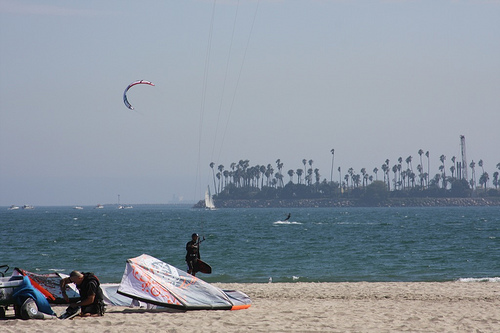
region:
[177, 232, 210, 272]
person wearing a black wet suit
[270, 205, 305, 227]
person water sailing in the water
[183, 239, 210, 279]
person wearing a black wet suiy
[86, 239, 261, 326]
para sail on the ground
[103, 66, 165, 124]
kite in the sky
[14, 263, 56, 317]
kite on the ground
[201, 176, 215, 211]
sailboat on the ocean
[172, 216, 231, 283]
person wearing all black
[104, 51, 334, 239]
he is kite surfing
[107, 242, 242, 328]
this is a sail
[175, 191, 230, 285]
he is carrying his board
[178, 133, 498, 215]
this is a islet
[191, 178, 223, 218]
the sail is white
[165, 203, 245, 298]
he is dressed in black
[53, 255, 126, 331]
he is kneeling in the sand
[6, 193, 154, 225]
these are speedboats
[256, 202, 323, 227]
he is surfing in the ocean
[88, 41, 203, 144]
object in the air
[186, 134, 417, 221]
palm trees in the distance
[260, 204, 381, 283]
water next to beach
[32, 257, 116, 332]
person on the beach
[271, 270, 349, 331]
sand on the beach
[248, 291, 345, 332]
footprints in the sand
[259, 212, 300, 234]
white water under man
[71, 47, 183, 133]
a parasail in the sky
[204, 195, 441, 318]
a body of water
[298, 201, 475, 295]
a body of calm water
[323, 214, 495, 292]
a body of water that is calm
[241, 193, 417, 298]
a body of blue water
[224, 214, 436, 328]
a body of water that is blue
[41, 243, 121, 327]
a man sitting on the beac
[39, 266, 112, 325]
a man sittin gon the sand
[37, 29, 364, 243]
a person parasailing ont he water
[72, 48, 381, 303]
a person that is parasailing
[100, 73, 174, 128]
para sail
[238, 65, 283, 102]
white clouds in blue sky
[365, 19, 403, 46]
white clouds in blue sky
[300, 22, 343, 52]
white clouds in blue sky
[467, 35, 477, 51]
white clouds in blue sky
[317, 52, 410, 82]
white clouds in blue sky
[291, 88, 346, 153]
white clouds in blue sky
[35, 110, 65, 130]
white clouds in blue sky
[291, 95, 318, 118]
white clouds in blue sky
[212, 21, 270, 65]
white clouds in blue sky